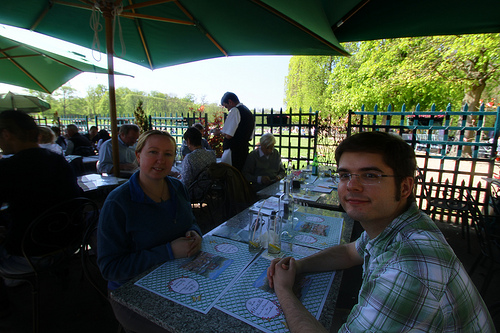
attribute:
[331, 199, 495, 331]
shirt — part of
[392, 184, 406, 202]
cheek — part of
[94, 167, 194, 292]
jacket — blue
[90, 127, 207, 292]
lady — sitting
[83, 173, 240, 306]
sweater — part of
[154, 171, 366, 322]
table — part of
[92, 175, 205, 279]
top — blue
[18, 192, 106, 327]
chair — black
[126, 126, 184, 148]
hair —  blonde, pulled back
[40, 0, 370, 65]
canopy — green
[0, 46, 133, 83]
canopy — green